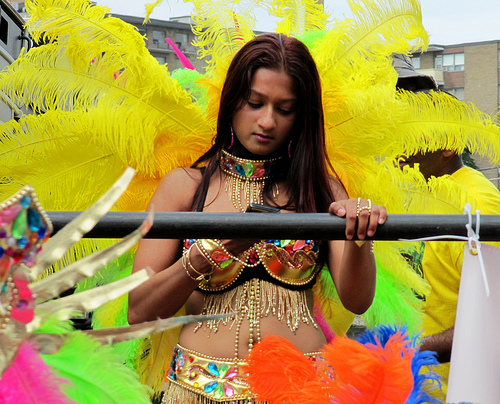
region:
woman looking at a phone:
[133, 24, 356, 402]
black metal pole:
[7, 183, 499, 244]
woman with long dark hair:
[206, 25, 341, 214]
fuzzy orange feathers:
[245, 330, 419, 401]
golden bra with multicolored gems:
[180, 198, 339, 306]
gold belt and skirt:
[158, 342, 350, 402]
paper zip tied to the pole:
[447, 200, 497, 402]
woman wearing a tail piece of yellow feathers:
[4, 1, 499, 292]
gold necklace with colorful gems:
[211, 139, 288, 185]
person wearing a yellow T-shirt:
[399, 83, 494, 385]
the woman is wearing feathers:
[12, 19, 440, 358]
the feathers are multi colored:
[3, 10, 423, 375]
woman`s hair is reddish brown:
[188, 16, 353, 210]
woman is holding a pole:
[282, 182, 419, 293]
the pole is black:
[186, 170, 418, 287]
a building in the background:
[89, 8, 490, 126]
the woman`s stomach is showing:
[164, 279, 340, 378]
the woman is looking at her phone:
[96, 35, 441, 312]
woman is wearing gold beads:
[182, 269, 317, 334]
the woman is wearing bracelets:
[161, 232, 227, 294]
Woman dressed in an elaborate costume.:
[21, 9, 496, 399]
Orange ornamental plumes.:
[250, 315, 411, 400]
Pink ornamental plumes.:
[0, 340, 55, 400]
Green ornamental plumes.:
[47, 307, 149, 399]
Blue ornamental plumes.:
[362, 318, 436, 402]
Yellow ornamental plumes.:
[10, 7, 477, 320]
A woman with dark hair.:
[196, 21, 335, 211]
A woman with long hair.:
[193, 24, 335, 220]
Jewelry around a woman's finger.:
[352, 193, 377, 218]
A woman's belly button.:
[243, 324, 260, 351]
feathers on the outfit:
[275, 351, 312, 388]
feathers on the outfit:
[332, 341, 397, 400]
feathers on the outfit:
[70, 353, 122, 400]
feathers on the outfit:
[18, 367, 49, 397]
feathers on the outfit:
[338, 91, 392, 142]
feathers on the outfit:
[106, 154, 149, 199]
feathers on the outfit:
[383, 333, 408, 353]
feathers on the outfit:
[43, 162, 68, 207]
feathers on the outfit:
[343, 76, 390, 126]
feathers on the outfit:
[386, 340, 426, 373]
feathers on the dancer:
[251, 339, 318, 393]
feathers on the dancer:
[341, 350, 376, 395]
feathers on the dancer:
[417, 351, 442, 395]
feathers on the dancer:
[388, 261, 409, 303]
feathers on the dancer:
[101, 361, 143, 395]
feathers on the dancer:
[24, 171, 86, 198]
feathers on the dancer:
[383, 115, 478, 152]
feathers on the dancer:
[335, 64, 378, 110]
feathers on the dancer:
[93, 60, 155, 105]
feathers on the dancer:
[198, 26, 218, 73]